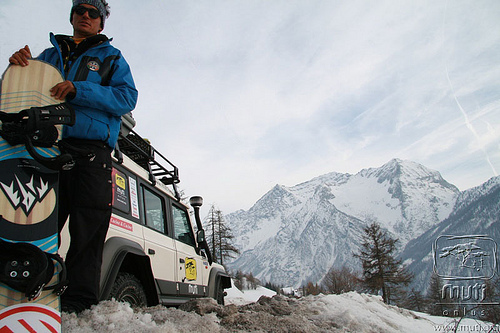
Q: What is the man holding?
A: A snow board.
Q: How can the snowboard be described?
A: As colorful.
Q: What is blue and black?
A: The man's jacket.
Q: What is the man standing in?
A: Snow.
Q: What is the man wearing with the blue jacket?
A: Black pants.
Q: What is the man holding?
A: A snowboard with a mountain graphic.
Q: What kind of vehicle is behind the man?
A: A white jeep with a roof rack.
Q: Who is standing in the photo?
A: A man in a blue coat.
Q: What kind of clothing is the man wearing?
A: Snowboarding gear.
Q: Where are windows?
A: On the jeep.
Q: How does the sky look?
A: Cloudy.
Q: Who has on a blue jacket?
A: The guy.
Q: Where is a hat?
A: On guy's head.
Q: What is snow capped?
A: Mountains.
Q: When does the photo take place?
A: During daytime.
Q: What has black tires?
A: Jeep.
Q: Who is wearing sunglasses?
A: The man.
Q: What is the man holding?
A: Snowboard.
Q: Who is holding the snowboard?
A: A man.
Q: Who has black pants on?
A: The man.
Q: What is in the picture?
A: A vehicle.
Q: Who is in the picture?
A: A man.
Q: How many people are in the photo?
A: One.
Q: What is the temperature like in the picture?
A: Cold.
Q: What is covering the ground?
A: Snow.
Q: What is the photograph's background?
A: Mountains.